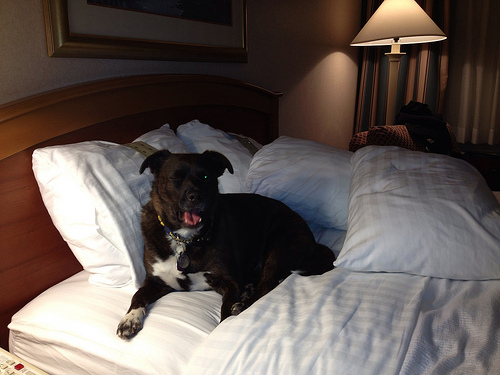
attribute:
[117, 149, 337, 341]
dog — sitting, white, brown, resting, lying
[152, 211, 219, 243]
collar — brown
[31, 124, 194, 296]
pillow — white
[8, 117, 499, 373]
bed — wooden, white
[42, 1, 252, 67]
picture — hanging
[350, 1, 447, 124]
lamp — background, white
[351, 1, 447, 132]
curtain — over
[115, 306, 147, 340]
paw — white, spotted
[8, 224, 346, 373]
sheets — white, grey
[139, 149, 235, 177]
ears — floppy